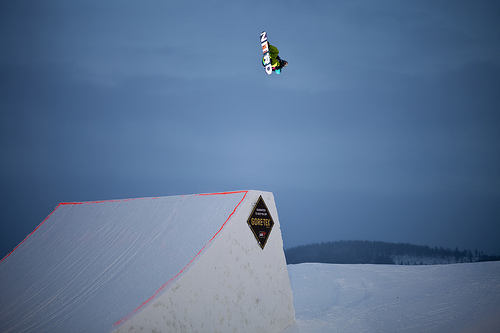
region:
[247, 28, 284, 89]
snow boarder doing trick in air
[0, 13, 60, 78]
white clouds in blue sky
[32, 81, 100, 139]
white clouds in blue sky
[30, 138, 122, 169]
white clouds in blue sky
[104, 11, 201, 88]
white clouds in blue sky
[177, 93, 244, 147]
white clouds in blue sky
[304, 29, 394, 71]
white clouds in blue sky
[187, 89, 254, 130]
white clouds in blue sky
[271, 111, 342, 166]
white clouds in blue sky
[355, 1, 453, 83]
white clouds in blue sky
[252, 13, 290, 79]
snow boarder in the air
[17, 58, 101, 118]
white clouds in blue sky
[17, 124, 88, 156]
white clouds in blue sky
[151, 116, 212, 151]
white clouds in blue sky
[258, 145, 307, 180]
white clouds in blue sky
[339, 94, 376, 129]
white clouds in blue sky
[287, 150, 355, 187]
white clouds in blue sky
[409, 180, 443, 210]
white clouds in blue sky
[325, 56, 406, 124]
white clouds in blue sky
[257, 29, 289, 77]
a flying snowboarder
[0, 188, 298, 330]
a snowy ramp ski ramp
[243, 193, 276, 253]
a black diamond shaped sign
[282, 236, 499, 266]
a line of trees in the distance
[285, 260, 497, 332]
a snowy slope with blue shadows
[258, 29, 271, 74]
the bottom of a snowboard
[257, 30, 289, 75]
a snowboarder dressed in green gear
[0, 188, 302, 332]
a snow ramp with edges marked in pink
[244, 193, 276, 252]
a black Gore Tex advertising sign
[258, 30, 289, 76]
a snowboarding completing a trick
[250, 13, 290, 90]
snowboarder in air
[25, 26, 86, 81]
white clouds in blue sky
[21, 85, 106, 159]
white clouds in blue sky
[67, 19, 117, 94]
white clouds in blue sky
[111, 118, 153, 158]
white clouds in blue sky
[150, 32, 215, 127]
white clouds in blue sky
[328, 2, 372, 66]
white clouds in blue sky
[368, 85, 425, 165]
white clouds in blue sky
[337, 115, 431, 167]
white clouds in blue sky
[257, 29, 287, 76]
Man flying through the air on a snowboard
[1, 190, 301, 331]
Tall white snowboarding ramp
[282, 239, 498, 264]
Hill of pine trees in the distance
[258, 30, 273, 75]
Nitro painted in white on a snowboard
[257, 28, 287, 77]
Person wearing yellow snowboarding gear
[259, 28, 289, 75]
Person doing tricks on a snowboard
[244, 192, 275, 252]
Black diamond shaped sign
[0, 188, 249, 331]
Red square outline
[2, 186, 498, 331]
Snowboarding ramp in the snow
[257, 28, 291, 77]
Person flying through the air on a snowboard